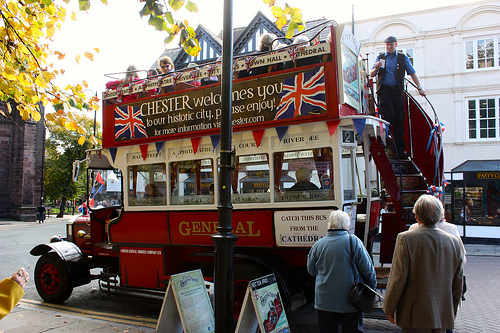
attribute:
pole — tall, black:
[211, 0, 235, 331]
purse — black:
[345, 233, 378, 310]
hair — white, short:
[294, 207, 396, 302]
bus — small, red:
[84, 39, 407, 332]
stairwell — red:
[361, 67, 444, 321]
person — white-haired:
[305, 210, 380, 328]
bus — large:
[29, 20, 444, 320]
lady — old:
[308, 210, 379, 330]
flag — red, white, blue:
[276, 71, 327, 116]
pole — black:
[223, 22, 230, 132]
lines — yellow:
[1, 294, 163, 330]